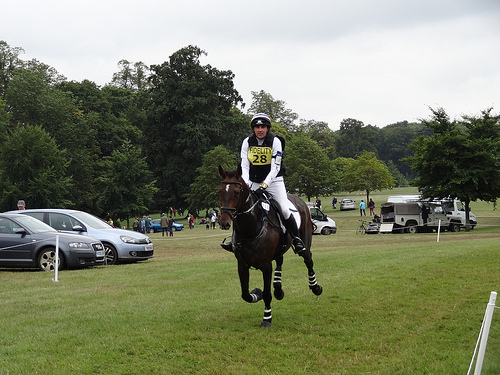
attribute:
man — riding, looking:
[240, 112, 304, 251]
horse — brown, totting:
[216, 163, 323, 328]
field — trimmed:
[1, 185, 499, 375]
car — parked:
[1, 213, 106, 271]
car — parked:
[17, 207, 156, 268]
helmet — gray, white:
[249, 111, 272, 129]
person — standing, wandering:
[357, 198, 368, 219]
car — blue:
[143, 217, 183, 234]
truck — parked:
[377, 204, 463, 238]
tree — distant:
[412, 109, 500, 232]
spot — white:
[225, 180, 230, 192]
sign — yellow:
[249, 146, 275, 167]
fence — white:
[1, 236, 61, 251]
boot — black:
[283, 211, 306, 255]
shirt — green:
[358, 202, 365, 211]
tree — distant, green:
[341, 150, 398, 209]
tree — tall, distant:
[283, 134, 344, 202]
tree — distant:
[95, 138, 159, 231]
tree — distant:
[1, 123, 77, 209]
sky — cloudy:
[1, 1, 500, 129]